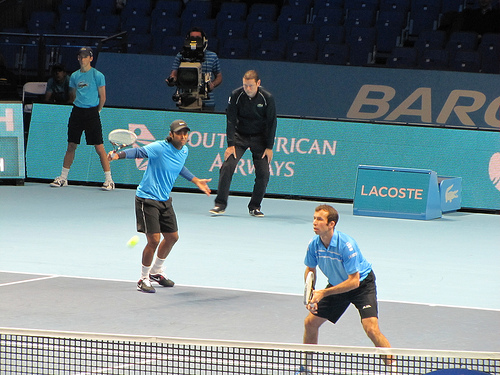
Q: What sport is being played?
A: Tennis.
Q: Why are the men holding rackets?
A: To play tennis.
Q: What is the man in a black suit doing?
A: Judging the game.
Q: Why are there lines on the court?
A: To mark boundaries.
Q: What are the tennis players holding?
A: Tennis rackets.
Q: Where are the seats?
A: Behind the court.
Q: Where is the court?
A: Under the men.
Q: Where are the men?
A: On the court.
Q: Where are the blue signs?
A: Behind the men.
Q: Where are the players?
A: On the tennis court.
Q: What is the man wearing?
A: A blue shirt and black shorts.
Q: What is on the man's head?
A: A black hat.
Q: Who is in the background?
A: A man dressed in all black.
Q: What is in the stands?
A: Empty seats.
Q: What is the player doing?
A: Bending forward.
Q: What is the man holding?
A: A tennis raquet.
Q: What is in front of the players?
A: A net.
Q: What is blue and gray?
A: The court.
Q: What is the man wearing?
A: Uniform.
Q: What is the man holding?
A: Racket.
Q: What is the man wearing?
A: Shorts.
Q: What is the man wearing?
A: Shirt.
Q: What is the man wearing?
A: Cap.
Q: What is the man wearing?
A: Shoes.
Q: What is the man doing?
A: Playign.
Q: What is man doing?
A: Standing.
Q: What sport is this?
A: Tennis.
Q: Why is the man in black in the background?
A: Referee.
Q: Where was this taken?
A: A on tennis court.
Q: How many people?
A: 6.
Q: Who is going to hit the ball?
A: The player on the left.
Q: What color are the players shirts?
A: Blue.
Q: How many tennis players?
A: 2.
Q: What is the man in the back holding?
A: A camera.